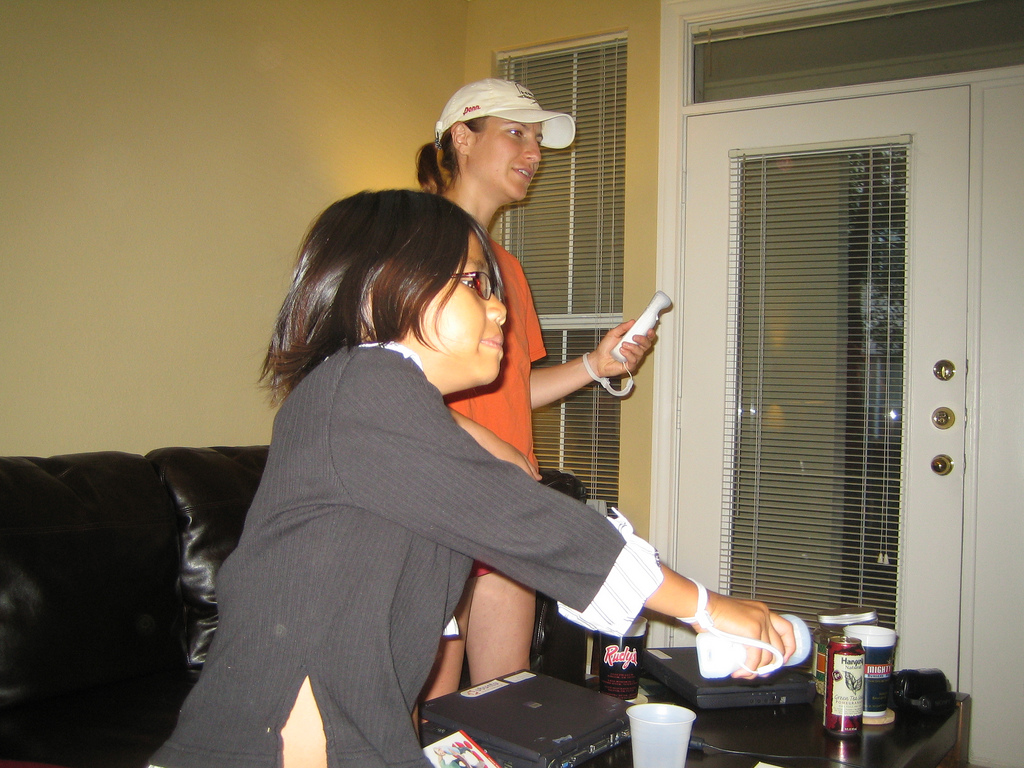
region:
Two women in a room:
[77, 23, 885, 764]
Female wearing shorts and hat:
[373, 46, 585, 736]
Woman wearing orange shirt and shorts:
[364, 43, 595, 705]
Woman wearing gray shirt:
[119, 143, 652, 754]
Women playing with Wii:
[118, 26, 935, 761]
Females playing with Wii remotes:
[111, 34, 963, 747]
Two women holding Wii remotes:
[92, 32, 922, 759]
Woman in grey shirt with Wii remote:
[134, 141, 884, 761]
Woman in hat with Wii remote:
[396, 81, 722, 710]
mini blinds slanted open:
[714, 124, 899, 665]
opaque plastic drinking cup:
[620, 696, 700, 766]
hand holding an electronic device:
[579, 288, 678, 402]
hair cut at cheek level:
[249, 181, 507, 410]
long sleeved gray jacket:
[145, 340, 627, 765]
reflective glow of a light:
[307, 58, 454, 196]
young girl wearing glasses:
[142, 182, 814, 765]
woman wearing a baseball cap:
[414, 73, 677, 704]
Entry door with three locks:
[669, 5, 977, 759]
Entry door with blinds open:
[671, 102, 954, 757]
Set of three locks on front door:
[914, 301, 969, 548]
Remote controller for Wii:
[566, 263, 703, 444]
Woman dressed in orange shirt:
[411, 64, 598, 733]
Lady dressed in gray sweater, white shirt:
[204, 151, 869, 766]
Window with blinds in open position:
[466, 21, 653, 559]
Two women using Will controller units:
[137, 21, 814, 767]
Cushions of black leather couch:
[8, 408, 421, 766]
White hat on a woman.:
[434, 77, 575, 151]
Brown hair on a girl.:
[152, 188, 795, 765]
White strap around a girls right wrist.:
[680, 577, 712, 629]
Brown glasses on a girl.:
[433, 267, 504, 302]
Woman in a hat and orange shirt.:
[417, 80, 662, 703]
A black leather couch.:
[0, 450, 590, 763]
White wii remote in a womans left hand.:
[613, 291, 675, 362]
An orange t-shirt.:
[447, 232, 549, 468]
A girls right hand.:
[699, 589, 797, 681]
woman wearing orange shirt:
[403, 76, 553, 681]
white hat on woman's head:
[432, 74, 575, 148]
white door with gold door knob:
[672, 101, 979, 727]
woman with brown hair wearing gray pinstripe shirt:
[160, 190, 796, 767]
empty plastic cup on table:
[625, 698, 702, 767]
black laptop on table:
[635, 633, 813, 714]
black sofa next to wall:
[1, 439, 591, 765]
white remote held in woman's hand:
[690, 586, 809, 678]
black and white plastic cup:
[595, 608, 649, 707]